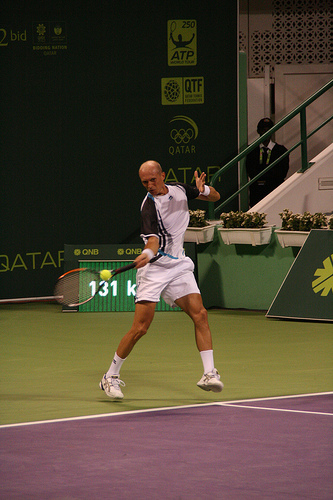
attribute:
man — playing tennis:
[95, 157, 226, 404]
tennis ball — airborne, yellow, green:
[99, 267, 113, 282]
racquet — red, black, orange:
[51, 253, 157, 311]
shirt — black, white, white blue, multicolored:
[133, 178, 199, 270]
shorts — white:
[133, 258, 203, 305]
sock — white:
[197, 347, 218, 379]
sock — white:
[106, 348, 129, 379]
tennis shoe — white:
[194, 369, 224, 395]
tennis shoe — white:
[97, 369, 125, 403]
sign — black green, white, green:
[58, 244, 202, 312]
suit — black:
[243, 140, 289, 206]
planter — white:
[181, 223, 215, 245]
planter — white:
[217, 225, 274, 248]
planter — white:
[272, 227, 310, 251]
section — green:
[2, 295, 333, 439]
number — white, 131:
[86, 280, 118, 301]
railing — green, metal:
[199, 75, 332, 214]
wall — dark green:
[0, 1, 245, 306]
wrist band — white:
[200, 182, 212, 198]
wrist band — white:
[141, 249, 162, 267]